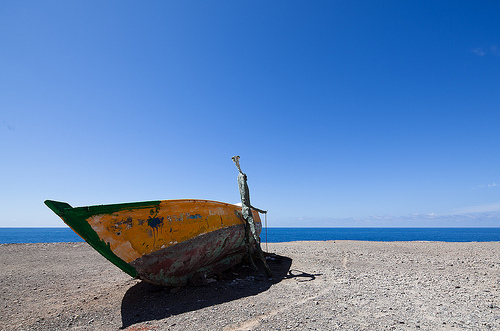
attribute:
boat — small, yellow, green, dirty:
[44, 156, 263, 294]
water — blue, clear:
[1, 227, 499, 243]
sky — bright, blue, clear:
[0, 1, 499, 229]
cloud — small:
[470, 45, 499, 59]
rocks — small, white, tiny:
[1, 240, 500, 331]